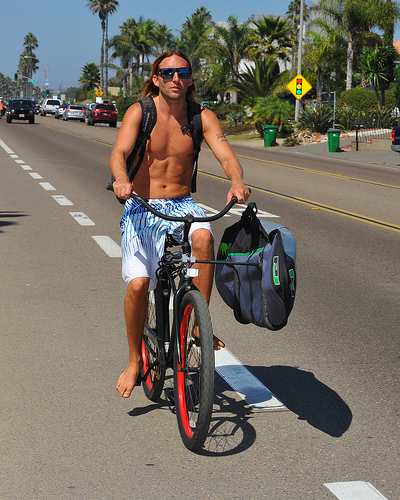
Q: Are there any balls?
A: No, there are no balls.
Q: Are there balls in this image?
A: No, there are no balls.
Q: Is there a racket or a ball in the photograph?
A: No, there are no balls or rackets.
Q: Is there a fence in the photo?
A: No, there are no fences.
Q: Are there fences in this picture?
A: No, there are no fences.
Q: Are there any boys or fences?
A: No, there are no fences or boys.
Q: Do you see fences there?
A: No, there are no fences.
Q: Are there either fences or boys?
A: No, there are no fences or boys.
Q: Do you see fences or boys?
A: No, there are no fences or boys.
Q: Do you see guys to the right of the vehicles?
A: Yes, there is a guy to the right of the vehicles.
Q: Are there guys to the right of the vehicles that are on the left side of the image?
A: Yes, there is a guy to the right of the vehicles.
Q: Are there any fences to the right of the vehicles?
A: No, there is a guy to the right of the vehicles.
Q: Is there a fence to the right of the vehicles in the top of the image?
A: No, there is a guy to the right of the vehicles.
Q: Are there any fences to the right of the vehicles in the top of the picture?
A: No, there is a guy to the right of the vehicles.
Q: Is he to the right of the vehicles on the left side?
A: Yes, the guy is to the right of the vehicles.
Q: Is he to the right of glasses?
A: No, the guy is to the right of the vehicles.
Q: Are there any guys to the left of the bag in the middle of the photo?
A: Yes, there is a guy to the left of the bag.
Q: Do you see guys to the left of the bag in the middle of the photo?
A: Yes, there is a guy to the left of the bag.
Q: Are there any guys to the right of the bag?
A: No, the guy is to the left of the bag.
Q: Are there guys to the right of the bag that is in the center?
A: No, the guy is to the left of the bag.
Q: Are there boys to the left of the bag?
A: No, there is a guy to the left of the bag.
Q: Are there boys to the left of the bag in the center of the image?
A: No, there is a guy to the left of the bag.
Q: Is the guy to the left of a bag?
A: Yes, the guy is to the left of a bag.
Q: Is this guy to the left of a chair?
A: No, the guy is to the left of a bag.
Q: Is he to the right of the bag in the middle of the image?
A: No, the guy is to the left of the bag.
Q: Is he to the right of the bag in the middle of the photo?
A: No, the guy is to the left of the bag.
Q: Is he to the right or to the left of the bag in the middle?
A: The guy is to the left of the bag.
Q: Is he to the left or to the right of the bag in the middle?
A: The guy is to the left of the bag.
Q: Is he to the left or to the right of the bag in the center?
A: The guy is to the left of the bag.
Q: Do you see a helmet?
A: No, there are no helmets.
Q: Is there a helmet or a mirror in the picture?
A: No, there are no helmets or mirrors.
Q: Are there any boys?
A: No, there are no boys.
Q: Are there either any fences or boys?
A: No, there are no boys or fences.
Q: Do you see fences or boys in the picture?
A: No, there are no boys or fences.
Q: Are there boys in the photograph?
A: No, there are no boys.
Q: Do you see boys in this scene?
A: No, there are no boys.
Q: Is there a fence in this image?
A: No, there are no fences.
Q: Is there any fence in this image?
A: No, there are no fences.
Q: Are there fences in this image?
A: No, there are no fences.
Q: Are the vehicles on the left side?
A: Yes, the vehicles are on the left of the image.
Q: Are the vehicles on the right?
A: No, the vehicles are on the left of the image.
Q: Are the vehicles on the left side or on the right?
A: The vehicles are on the left of the image.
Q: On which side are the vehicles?
A: The vehicles are on the left of the image.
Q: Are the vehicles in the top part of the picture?
A: Yes, the vehicles are in the top of the image.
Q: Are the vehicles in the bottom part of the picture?
A: No, the vehicles are in the top of the image.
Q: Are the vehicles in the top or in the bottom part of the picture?
A: The vehicles are in the top of the image.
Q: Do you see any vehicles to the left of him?
A: Yes, there are vehicles to the left of the guy.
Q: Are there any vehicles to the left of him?
A: Yes, there are vehicles to the left of the guy.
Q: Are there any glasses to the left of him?
A: No, there are vehicles to the left of the guy.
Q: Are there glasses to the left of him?
A: No, there are vehicles to the left of the guy.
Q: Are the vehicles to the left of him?
A: Yes, the vehicles are to the left of a guy.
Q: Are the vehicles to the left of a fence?
A: No, the vehicles are to the left of a guy.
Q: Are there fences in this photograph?
A: No, there are no fences.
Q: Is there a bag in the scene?
A: Yes, there is a bag.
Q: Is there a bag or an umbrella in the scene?
A: Yes, there is a bag.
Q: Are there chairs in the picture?
A: No, there are no chairs.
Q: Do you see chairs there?
A: No, there are no chairs.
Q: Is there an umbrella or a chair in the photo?
A: No, there are no chairs or umbrellas.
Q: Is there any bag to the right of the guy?
A: Yes, there is a bag to the right of the guy.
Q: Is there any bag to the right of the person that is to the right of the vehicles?
A: Yes, there is a bag to the right of the guy.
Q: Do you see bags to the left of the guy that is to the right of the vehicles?
A: No, the bag is to the right of the guy.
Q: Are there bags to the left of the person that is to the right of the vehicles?
A: No, the bag is to the right of the guy.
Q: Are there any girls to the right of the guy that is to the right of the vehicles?
A: No, there is a bag to the right of the guy.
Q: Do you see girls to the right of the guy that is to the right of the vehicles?
A: No, there is a bag to the right of the guy.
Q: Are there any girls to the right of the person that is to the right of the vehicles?
A: No, there is a bag to the right of the guy.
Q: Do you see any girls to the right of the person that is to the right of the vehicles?
A: No, there is a bag to the right of the guy.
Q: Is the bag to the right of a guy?
A: Yes, the bag is to the right of a guy.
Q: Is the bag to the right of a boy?
A: No, the bag is to the right of a guy.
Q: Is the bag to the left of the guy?
A: No, the bag is to the right of the guy.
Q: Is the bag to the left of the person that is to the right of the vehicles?
A: No, the bag is to the right of the guy.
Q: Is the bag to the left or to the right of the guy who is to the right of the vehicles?
A: The bag is to the right of the guy.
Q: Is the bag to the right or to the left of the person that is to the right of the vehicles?
A: The bag is to the right of the guy.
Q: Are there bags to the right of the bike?
A: Yes, there is a bag to the right of the bike.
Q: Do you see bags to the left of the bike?
A: No, the bag is to the right of the bike.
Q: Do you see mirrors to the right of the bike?
A: No, there is a bag to the right of the bike.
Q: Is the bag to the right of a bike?
A: Yes, the bag is to the right of a bike.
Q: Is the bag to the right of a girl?
A: No, the bag is to the right of a bike.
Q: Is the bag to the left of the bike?
A: No, the bag is to the right of the bike.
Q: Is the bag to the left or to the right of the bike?
A: The bag is to the right of the bike.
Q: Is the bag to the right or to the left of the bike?
A: The bag is to the right of the bike.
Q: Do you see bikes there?
A: Yes, there is a bike.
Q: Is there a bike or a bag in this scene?
A: Yes, there is a bike.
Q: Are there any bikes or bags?
A: Yes, there is a bike.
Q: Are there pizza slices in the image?
A: No, there are no pizza slices.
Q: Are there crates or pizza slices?
A: No, there are no pizza slices or crates.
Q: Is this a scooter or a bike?
A: This is a bike.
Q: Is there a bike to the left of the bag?
A: Yes, there is a bike to the left of the bag.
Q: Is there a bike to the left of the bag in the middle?
A: Yes, there is a bike to the left of the bag.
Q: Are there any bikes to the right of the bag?
A: No, the bike is to the left of the bag.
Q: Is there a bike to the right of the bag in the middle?
A: No, the bike is to the left of the bag.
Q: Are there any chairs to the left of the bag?
A: No, there is a bike to the left of the bag.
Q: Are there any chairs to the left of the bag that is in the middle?
A: No, there is a bike to the left of the bag.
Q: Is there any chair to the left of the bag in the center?
A: No, there is a bike to the left of the bag.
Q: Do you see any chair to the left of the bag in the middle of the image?
A: No, there is a bike to the left of the bag.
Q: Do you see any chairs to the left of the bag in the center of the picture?
A: No, there is a bike to the left of the bag.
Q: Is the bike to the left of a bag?
A: Yes, the bike is to the left of a bag.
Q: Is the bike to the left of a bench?
A: No, the bike is to the left of a bag.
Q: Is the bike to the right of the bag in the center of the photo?
A: No, the bike is to the left of the bag.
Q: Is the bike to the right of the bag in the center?
A: No, the bike is to the left of the bag.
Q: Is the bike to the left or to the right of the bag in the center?
A: The bike is to the left of the bag.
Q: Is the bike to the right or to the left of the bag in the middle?
A: The bike is to the left of the bag.